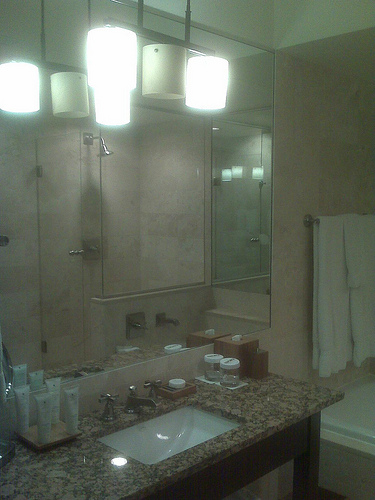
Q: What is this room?
A: It is a bathroom.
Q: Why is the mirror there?
A: So people can see themselves.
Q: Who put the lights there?
A: The owner of the house.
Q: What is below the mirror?
A: A sink.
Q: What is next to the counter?
A: A bathtub.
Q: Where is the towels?
A: Above the tub.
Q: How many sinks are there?
A: One.